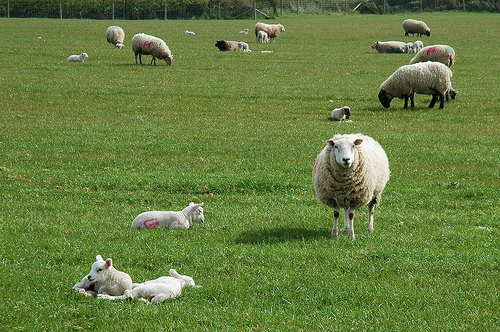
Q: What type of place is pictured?
A: It is a field.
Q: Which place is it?
A: It is a field.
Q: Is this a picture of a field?
A: Yes, it is showing a field.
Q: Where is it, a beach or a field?
A: It is a field.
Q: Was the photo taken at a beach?
A: No, the picture was taken in a field.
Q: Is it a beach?
A: No, it is a field.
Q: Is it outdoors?
A: Yes, it is outdoors.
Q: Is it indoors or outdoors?
A: It is outdoors.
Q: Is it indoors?
A: No, it is outdoors.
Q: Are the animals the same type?
A: Yes, all the animals are sheep.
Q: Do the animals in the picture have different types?
A: No, all the animals are sheep.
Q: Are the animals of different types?
A: No, all the animals are sheep.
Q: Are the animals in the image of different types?
A: No, all the animals are sheep.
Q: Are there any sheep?
A: Yes, there is a sheep.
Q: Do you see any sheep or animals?
A: Yes, there is a sheep.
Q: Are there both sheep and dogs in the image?
A: No, there is a sheep but no dogs.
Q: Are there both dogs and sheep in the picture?
A: No, there is a sheep but no dogs.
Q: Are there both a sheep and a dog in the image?
A: No, there is a sheep but no dogs.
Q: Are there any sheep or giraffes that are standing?
A: Yes, the sheep is standing.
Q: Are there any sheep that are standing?
A: Yes, there is a sheep that is standing.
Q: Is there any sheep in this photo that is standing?
A: Yes, there is a sheep that is standing.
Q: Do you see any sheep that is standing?
A: Yes, there is a sheep that is standing.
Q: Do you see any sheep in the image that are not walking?
A: Yes, there is a sheep that is standing .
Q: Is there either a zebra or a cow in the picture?
A: No, there are no zebras or cows.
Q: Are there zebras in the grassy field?
A: No, there is a sheep in the field.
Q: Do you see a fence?
A: Yes, there is a fence.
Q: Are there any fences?
A: Yes, there is a fence.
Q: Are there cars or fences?
A: Yes, there is a fence.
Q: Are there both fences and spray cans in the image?
A: No, there is a fence but no spray cans.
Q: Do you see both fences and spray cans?
A: No, there is a fence but no spray cans.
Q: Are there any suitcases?
A: No, there are no suitcases.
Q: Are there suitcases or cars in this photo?
A: No, there are no suitcases or cars.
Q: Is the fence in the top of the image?
A: Yes, the fence is in the top of the image.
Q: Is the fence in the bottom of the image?
A: No, the fence is in the top of the image.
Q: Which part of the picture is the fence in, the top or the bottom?
A: The fence is in the top of the image.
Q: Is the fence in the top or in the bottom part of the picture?
A: The fence is in the top of the image.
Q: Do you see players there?
A: No, there are no players.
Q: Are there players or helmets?
A: No, there are no players or helmets.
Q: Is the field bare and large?
A: No, the field is large but grassy.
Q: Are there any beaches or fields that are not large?
A: No, there is a field but it is large.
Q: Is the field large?
A: Yes, the field is large.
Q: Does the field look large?
A: Yes, the field is large.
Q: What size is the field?
A: The field is large.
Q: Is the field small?
A: No, the field is large.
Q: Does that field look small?
A: No, the field is large.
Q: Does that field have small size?
A: No, the field is large.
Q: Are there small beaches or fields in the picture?
A: No, there is a field but it is large.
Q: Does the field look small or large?
A: The field is large.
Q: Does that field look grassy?
A: Yes, the field is grassy.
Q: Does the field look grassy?
A: Yes, the field is grassy.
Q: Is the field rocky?
A: No, the field is grassy.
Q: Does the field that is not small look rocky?
A: No, the field is grassy.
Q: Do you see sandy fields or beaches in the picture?
A: No, there is a field but it is grassy.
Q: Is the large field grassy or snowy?
A: The field is grassy.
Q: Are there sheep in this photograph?
A: Yes, there is a sheep.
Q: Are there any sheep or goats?
A: Yes, there is a sheep.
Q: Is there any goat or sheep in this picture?
A: Yes, there is a sheep.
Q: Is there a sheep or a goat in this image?
A: Yes, there is a sheep.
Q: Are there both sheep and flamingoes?
A: No, there is a sheep but no flamingoes.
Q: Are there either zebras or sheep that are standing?
A: Yes, the sheep is standing.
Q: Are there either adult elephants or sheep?
A: Yes, there is an adult sheep.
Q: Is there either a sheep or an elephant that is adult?
A: Yes, the sheep is adult.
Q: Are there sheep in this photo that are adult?
A: Yes, there is an adult sheep.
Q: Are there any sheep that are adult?
A: Yes, there is a sheep that is adult.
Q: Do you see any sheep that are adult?
A: Yes, there is a sheep that is adult.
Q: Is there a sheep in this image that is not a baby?
A: Yes, there is a adult sheep.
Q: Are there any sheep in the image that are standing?
A: Yes, there is a sheep that is standing.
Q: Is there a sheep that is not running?
A: Yes, there is a sheep that is standing.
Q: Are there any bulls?
A: No, there are no bulls.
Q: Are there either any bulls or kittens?
A: No, there are no bulls or kittens.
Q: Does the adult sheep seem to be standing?
A: Yes, the sheep is standing.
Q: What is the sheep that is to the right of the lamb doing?
A: The sheep is standing.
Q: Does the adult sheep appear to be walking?
A: No, the sheep is standing.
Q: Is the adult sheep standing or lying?
A: The sheep is standing.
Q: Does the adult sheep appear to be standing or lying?
A: The sheep is standing.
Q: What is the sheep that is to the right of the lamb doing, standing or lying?
A: The sheep is standing.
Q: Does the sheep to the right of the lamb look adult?
A: Yes, the sheep is adult.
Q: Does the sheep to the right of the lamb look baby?
A: No, the sheep is adult.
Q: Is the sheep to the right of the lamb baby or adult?
A: The sheep is adult.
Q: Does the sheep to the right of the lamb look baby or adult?
A: The sheep is adult.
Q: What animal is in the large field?
A: The animal is a sheep.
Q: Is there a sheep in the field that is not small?
A: Yes, there is a sheep in the field.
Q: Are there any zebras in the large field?
A: No, there is a sheep in the field.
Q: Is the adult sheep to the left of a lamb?
A: No, the sheep is to the right of a lamb.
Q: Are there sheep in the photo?
A: Yes, there is a sheep.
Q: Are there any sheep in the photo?
A: Yes, there is a sheep.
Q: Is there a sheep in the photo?
A: Yes, there is a sheep.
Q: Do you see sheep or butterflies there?
A: Yes, there is a sheep.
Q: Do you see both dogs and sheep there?
A: No, there is a sheep but no dogs.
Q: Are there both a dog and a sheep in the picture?
A: No, there is a sheep but no dogs.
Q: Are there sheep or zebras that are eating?
A: Yes, the sheep is eating.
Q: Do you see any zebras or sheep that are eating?
A: Yes, the sheep is eating.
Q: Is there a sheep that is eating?
A: Yes, there is a sheep that is eating.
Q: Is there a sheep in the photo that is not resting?
A: Yes, there is a sheep that is eating.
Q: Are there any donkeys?
A: No, there are no donkeys.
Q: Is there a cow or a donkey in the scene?
A: No, there are no donkeys or cows.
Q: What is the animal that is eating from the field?
A: The animal is a sheep.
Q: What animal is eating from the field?
A: The animal is a sheep.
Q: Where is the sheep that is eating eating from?
A: The sheep is eating from the field.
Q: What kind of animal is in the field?
A: The animal is a sheep.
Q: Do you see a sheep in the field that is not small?
A: Yes, there is a sheep in the field.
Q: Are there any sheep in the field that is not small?
A: Yes, there is a sheep in the field.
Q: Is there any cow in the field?
A: No, there is a sheep in the field.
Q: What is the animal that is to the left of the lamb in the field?
A: The animal is a sheep.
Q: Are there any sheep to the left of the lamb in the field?
A: Yes, there is a sheep to the left of the lamb.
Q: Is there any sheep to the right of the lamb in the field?
A: No, the sheep is to the left of the lamb.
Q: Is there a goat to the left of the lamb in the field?
A: No, there is a sheep to the left of the lamb.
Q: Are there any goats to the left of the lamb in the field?
A: No, there is a sheep to the left of the lamb.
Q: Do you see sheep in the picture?
A: Yes, there is a sheep.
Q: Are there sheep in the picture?
A: Yes, there is a sheep.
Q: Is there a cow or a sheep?
A: Yes, there is a sheep.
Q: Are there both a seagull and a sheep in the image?
A: No, there is a sheep but no seagulls.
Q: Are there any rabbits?
A: No, there are no rabbits.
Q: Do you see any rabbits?
A: No, there are no rabbits.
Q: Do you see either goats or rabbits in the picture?
A: No, there are no rabbits or goats.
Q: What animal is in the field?
A: The animal is a sheep.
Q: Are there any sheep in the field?
A: Yes, there is a sheep in the field.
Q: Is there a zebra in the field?
A: No, there is a sheep in the field.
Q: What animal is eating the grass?
A: The sheep is eating the grass.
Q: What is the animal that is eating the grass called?
A: The animal is a sheep.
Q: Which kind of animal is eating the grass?
A: The animal is a sheep.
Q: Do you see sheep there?
A: Yes, there is a sheep.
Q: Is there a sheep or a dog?
A: Yes, there is a sheep.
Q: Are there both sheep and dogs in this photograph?
A: No, there is a sheep but no dogs.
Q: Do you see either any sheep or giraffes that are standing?
A: Yes, the sheep is standing.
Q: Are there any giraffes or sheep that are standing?
A: Yes, the sheep is standing.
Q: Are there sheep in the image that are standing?
A: Yes, there is a sheep that is standing.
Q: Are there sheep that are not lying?
A: Yes, there is a sheep that is standing.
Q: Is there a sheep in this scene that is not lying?
A: Yes, there is a sheep that is standing.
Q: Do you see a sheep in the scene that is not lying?
A: Yes, there is a sheep that is standing .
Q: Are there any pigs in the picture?
A: No, there are no pigs.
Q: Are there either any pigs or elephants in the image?
A: No, there are no pigs or elephants.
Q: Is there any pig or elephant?
A: No, there are no pigs or elephants.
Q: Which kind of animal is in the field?
A: The animal is a sheep.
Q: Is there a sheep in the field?
A: Yes, there is a sheep in the field.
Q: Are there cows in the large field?
A: No, there is a sheep in the field.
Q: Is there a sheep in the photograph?
A: Yes, there is a sheep.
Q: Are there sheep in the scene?
A: Yes, there is a sheep.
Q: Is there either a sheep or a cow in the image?
A: Yes, there is a sheep.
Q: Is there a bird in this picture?
A: No, there are no birds.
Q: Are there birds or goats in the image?
A: No, there are no birds or goats.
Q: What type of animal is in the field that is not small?
A: The animal is a sheep.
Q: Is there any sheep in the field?
A: Yes, there is a sheep in the field.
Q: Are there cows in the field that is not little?
A: No, there is a sheep in the field.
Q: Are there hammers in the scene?
A: No, there are no hammers.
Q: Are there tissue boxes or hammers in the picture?
A: No, there are no hammers or tissue boxes.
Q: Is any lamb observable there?
A: Yes, there is a lamb.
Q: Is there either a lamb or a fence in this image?
A: Yes, there is a lamb.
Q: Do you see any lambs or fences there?
A: Yes, there is a lamb.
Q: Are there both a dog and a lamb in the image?
A: No, there is a lamb but no dogs.